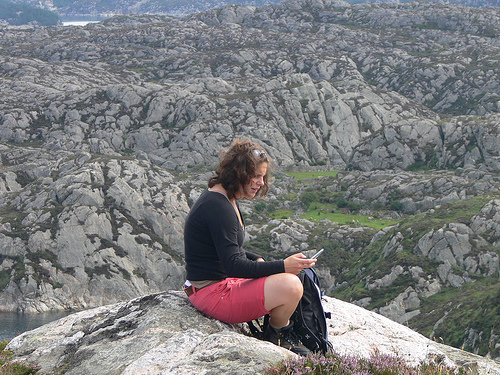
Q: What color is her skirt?
A: Pink.